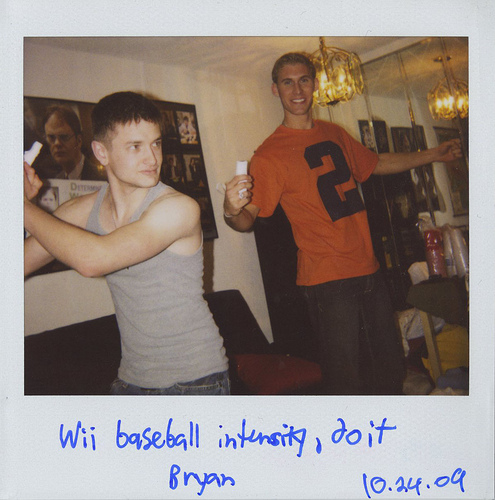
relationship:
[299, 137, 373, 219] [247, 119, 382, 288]
2 on top of shirt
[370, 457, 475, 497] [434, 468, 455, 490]
10.24.09 in handwriting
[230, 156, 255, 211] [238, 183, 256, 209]
controller for wii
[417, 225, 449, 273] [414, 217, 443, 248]
cups are in a stack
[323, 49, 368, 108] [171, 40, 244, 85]
lights hanging from ceiling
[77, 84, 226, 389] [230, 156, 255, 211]
man swinging controller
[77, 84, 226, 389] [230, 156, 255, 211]
man holding controller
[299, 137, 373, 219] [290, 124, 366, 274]
2 on top of shirt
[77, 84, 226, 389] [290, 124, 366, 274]
man wearing shirt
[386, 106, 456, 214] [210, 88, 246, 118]
mirrors attached to wall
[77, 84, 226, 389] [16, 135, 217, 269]
man in batter stand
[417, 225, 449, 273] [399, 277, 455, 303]
cups on top of table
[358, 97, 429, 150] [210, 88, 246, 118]
mirror attached to wall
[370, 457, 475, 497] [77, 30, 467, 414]
date of picture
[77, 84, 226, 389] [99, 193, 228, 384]
man wearing tank top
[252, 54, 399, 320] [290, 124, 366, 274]
man wearing shirt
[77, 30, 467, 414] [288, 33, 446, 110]
people are in room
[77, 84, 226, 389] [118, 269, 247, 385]
man wearing undershirt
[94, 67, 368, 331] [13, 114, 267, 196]
men holding controllers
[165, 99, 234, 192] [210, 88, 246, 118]
images hanging from wall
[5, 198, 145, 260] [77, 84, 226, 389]
arms of man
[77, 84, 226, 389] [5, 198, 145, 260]
man holding arms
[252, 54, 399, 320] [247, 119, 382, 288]
man wearing shirt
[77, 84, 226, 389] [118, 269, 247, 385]
boy wearing undershirt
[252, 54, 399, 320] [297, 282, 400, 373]
boy wearing pants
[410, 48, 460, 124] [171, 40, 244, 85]
chandler hanging from ceiling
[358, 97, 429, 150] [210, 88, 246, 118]
mirror covering wall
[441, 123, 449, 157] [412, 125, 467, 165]
candle in hand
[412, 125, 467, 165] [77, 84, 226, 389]
hand of man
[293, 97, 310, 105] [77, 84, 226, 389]
mouth of man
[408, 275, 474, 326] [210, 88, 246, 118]
shelf attached to wall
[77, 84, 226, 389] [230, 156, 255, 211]
man holding remote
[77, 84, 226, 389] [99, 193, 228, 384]
man wearing wife beater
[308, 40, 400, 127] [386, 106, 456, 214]
chandelier near mirrors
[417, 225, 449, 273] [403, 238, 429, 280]
cups next to cups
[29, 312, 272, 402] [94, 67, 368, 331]
sofa behind men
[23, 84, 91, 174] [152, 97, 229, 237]
picture inside of frame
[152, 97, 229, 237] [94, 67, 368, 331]
frame behind men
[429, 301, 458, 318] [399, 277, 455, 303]
tablecloth on top of table